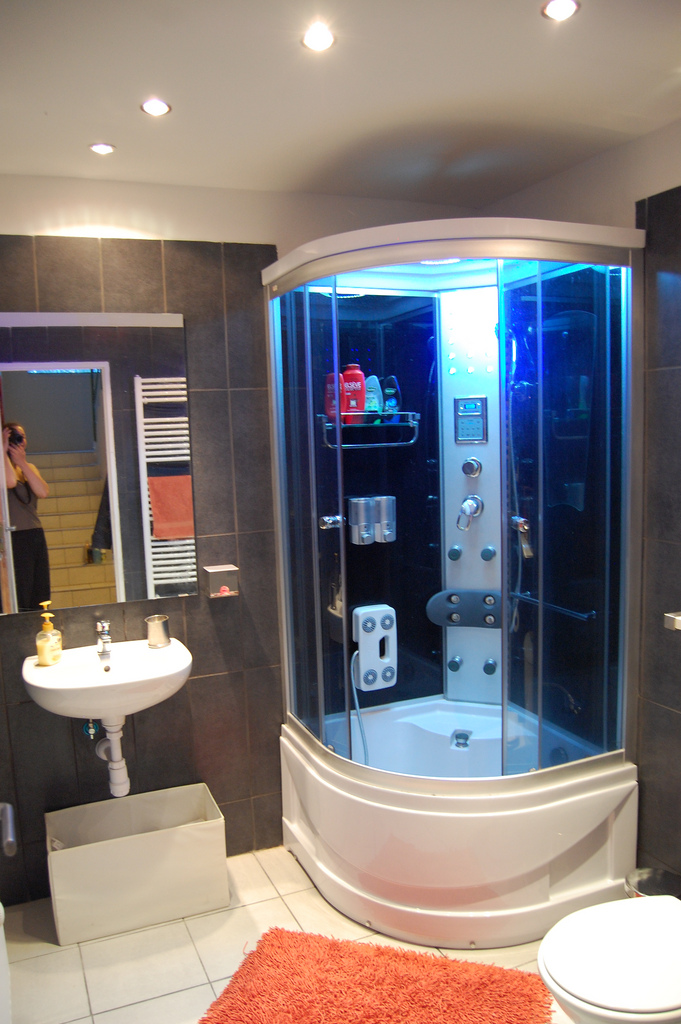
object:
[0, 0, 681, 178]
ceiling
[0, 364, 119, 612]
mirror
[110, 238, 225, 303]
wall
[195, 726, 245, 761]
wall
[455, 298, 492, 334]
light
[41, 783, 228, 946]
tub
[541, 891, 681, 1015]
lid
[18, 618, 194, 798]
sink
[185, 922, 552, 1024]
rug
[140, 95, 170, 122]
light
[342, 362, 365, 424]
bottle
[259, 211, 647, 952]
shoer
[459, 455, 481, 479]
knob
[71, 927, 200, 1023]
tile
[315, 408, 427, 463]
shelf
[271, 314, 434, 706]
wall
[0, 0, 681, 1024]
bathroom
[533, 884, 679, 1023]
toilet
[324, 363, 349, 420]
bottles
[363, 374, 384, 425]
bottles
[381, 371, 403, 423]
bottle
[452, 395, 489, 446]
controls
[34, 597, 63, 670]
bottle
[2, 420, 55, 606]
woman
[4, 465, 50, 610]
dress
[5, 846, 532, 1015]
floor